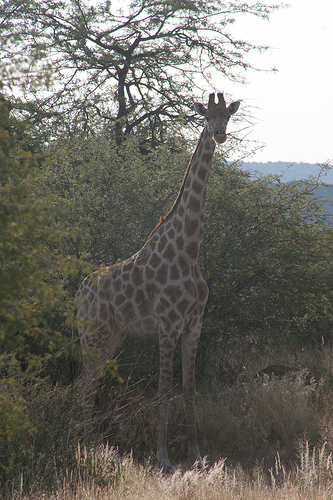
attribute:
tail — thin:
[68, 303, 80, 355]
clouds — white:
[280, 49, 322, 130]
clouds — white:
[279, 43, 294, 79]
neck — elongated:
[156, 123, 215, 247]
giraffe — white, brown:
[31, 69, 255, 483]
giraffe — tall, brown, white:
[55, 85, 251, 470]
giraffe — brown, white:
[24, 78, 267, 478]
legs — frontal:
[144, 305, 211, 490]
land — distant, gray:
[223, 154, 331, 198]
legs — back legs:
[60, 301, 106, 478]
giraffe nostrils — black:
[199, 124, 238, 159]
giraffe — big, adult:
[72, 85, 245, 477]